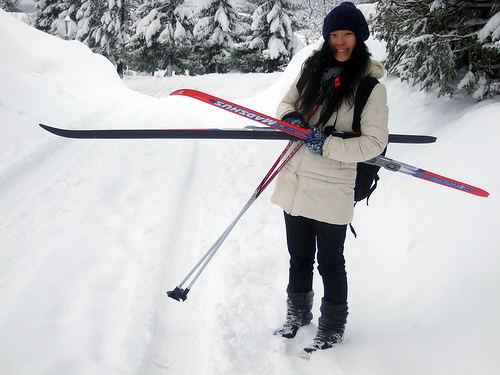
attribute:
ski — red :
[169, 88, 490, 198]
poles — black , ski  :
[147, 132, 289, 342]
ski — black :
[37, 124, 441, 146]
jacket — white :
[269, 50, 390, 226]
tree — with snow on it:
[244, 0, 299, 70]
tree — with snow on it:
[189, 1, 239, 71]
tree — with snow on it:
[132, 1, 192, 73]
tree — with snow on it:
[86, 0, 139, 70]